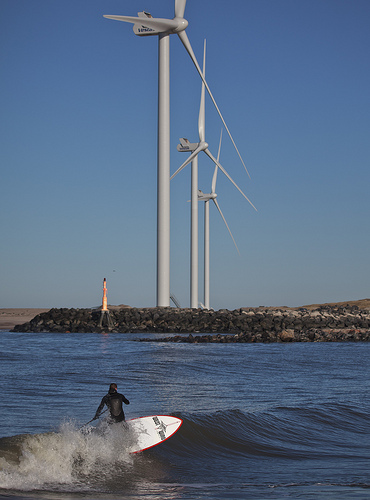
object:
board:
[101, 412, 183, 454]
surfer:
[94, 381, 132, 425]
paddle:
[77, 407, 109, 431]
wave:
[0, 397, 370, 500]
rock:
[350, 307, 362, 317]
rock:
[303, 329, 317, 340]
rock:
[257, 320, 278, 330]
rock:
[127, 307, 143, 317]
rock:
[149, 311, 163, 323]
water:
[1, 331, 369, 498]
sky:
[1, 1, 369, 313]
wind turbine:
[100, 1, 258, 309]